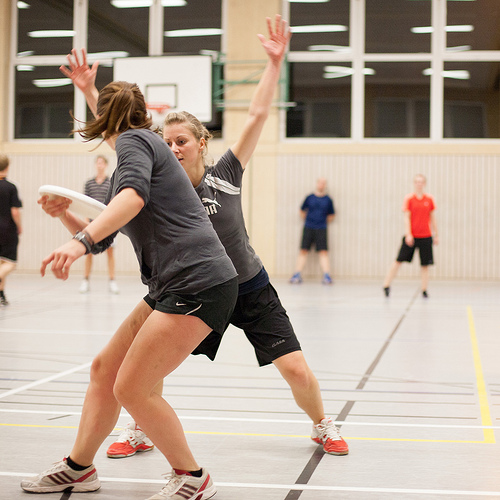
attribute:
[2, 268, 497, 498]
court — full of lines, full of white lines, full of yellow lines, full of black lines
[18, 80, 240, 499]
girl — wearing dark shirt, wearing black watch, wearing wrist band, holding the frisbee, one of the players, playing frisbee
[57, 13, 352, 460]
girl — wearing red sneakers, one of the players, playing frisbee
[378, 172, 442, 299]
girl — wearing black shorts, wearing red, black, wearing a red shirt, wearing black shoes, wearing red playing, playing frisbee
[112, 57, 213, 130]
basketball hoop — large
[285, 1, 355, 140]
gymnasium window — inside the gym, very large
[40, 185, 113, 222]
frisbee — white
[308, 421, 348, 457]
left shoe — red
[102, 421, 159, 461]
red shoe — on right foot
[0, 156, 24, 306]
woman — wearing black shorts